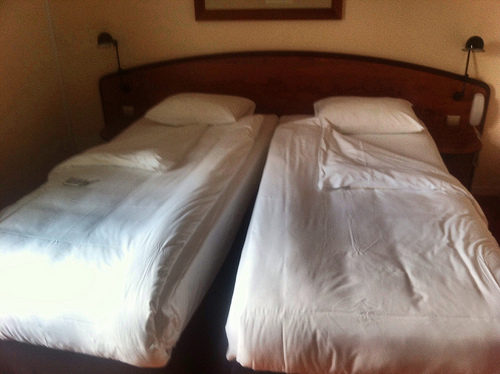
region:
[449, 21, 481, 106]
small black bedside lamp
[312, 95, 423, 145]
white average pillow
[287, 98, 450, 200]
bed with comforter pulled back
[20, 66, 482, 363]
two twin size beds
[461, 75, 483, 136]
white bedside telephone with cord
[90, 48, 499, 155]
wooden bed head board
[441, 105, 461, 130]
white bedside light switch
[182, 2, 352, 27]
hotel room picture frame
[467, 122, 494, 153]
white telephone cord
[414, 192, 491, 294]
wrinkles on a white comforter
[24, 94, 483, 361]
the beds are white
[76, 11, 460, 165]
the headboards are brown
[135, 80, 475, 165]
the pillows are white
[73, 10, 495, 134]
the headboard has lamps on it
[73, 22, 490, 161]
the lamps are black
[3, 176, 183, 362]
the sun is shining on the bed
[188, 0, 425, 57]
a picture frame is above the beds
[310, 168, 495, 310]
the bed has wrinkles in it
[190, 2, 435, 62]
the picture frame is brown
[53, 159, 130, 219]
an object is on the left bed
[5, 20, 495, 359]
Two beds in the room.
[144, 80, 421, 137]
Pillows on the bed.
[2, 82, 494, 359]
The sheets are white.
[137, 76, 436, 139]
The pillows are white.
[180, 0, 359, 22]
Picture hanging on the wall.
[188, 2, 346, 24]
The picture frame is brown.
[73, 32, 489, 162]
The headboard is brown.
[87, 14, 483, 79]
Two lamps on the headboard.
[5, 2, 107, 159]
The wall is white.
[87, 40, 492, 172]
The headboard is wooden.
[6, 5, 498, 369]
two twin beds in a bedroom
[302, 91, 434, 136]
white pillow on the bed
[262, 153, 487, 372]
white comforter on a bed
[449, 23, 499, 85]
lamp to the side of the bed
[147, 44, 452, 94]
wooden headboard of the beds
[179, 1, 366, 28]
framed artwork on the wall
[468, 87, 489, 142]
white telephone on the headboard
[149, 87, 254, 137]
white pillow on the left bed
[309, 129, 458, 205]
triangle made from folded comforter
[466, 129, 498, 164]
wire from the telephone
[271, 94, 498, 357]
white sheets and pillow on a bed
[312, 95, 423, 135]
white pillow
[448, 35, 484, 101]
black lamp on the wooden headboard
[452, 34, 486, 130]
white object near the black lamp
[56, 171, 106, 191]
object on the bed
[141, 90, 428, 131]
two pillows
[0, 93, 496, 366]
two white beds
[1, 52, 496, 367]
double beds with a wooden headboard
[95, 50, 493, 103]
brown wooden headboard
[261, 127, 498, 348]
white bed sheet